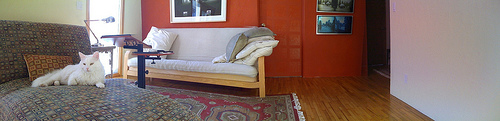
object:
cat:
[30, 51, 106, 88]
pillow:
[23, 54, 75, 82]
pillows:
[211, 26, 280, 66]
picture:
[316, 0, 355, 14]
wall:
[141, 0, 368, 78]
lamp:
[83, 16, 115, 47]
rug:
[130, 84, 307, 121]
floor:
[106, 75, 435, 121]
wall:
[389, 0, 498, 121]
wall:
[1, 0, 87, 26]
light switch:
[75, 0, 85, 10]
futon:
[121, 26, 267, 98]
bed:
[0, 20, 203, 121]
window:
[88, 0, 122, 78]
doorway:
[364, 0, 390, 81]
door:
[259, 0, 368, 78]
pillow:
[143, 25, 179, 60]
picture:
[315, 15, 354, 35]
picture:
[169, 0, 226, 23]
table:
[90, 46, 117, 79]